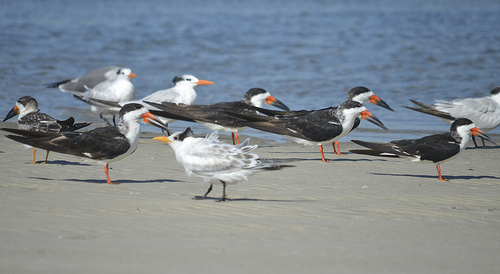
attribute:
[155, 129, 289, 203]
bird — white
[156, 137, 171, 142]
beak — yellow, orange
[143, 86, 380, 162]
birds — black, white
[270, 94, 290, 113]
beaks — orange, black, long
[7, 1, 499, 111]
water — blue, choppy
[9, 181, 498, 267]
sand — smooth, gray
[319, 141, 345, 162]
feet — orange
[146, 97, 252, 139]
wings — black, dark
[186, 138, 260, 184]
feathers — ruffled, white, black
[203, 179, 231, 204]
legs — black, dark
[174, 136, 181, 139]
eye — black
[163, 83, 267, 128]
feathers — black, long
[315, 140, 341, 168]
legs — orange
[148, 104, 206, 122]
tail — black